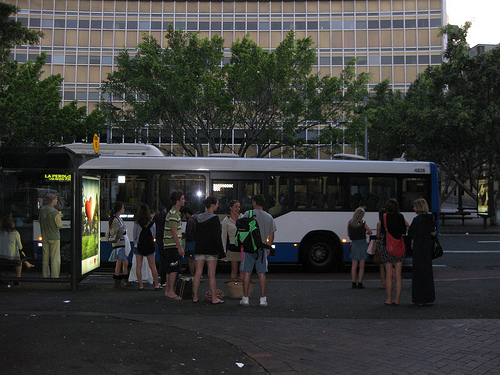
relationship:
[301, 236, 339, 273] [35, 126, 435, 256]
back tire of bus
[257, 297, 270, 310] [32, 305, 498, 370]
sneaker on pavement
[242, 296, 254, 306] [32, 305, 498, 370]
sneaker on pavement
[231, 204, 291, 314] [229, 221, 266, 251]
man carrying backpack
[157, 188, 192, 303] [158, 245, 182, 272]
man wearing black shorts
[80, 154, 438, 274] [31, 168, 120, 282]
bus at bus stop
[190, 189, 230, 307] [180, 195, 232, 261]
woman wearing hoodie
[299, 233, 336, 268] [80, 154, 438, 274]
back tire on bus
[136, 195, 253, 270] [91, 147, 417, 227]
people near bus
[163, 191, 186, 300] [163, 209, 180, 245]
man wearing shirt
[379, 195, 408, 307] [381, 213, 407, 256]
woman has red purse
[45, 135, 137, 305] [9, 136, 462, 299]
advertisement at bus stop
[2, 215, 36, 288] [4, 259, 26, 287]
woman sitting on bench